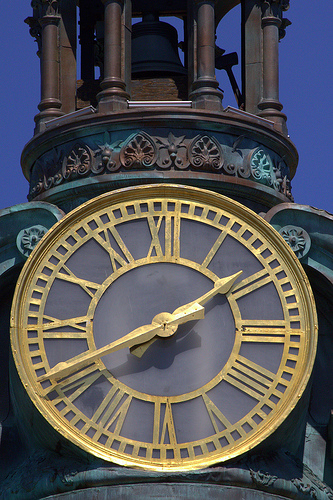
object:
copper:
[20, 107, 299, 206]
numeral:
[231, 269, 273, 301]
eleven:
[92, 226, 135, 273]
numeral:
[202, 391, 231, 433]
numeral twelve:
[146, 214, 181, 259]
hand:
[128, 270, 243, 357]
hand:
[36, 302, 205, 383]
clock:
[8, 183, 318, 472]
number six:
[152, 402, 177, 444]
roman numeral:
[224, 354, 276, 400]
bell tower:
[0, 1, 333, 500]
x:
[55, 265, 101, 299]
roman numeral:
[241, 319, 285, 342]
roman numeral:
[43, 316, 86, 338]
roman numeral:
[90, 385, 132, 436]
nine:
[41, 314, 87, 338]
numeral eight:
[57, 362, 100, 403]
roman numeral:
[55, 264, 101, 296]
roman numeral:
[202, 231, 228, 268]